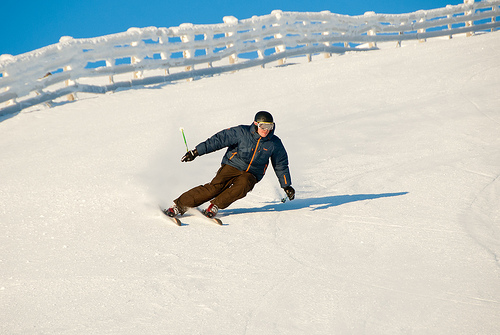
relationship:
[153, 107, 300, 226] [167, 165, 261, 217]
man wearing pants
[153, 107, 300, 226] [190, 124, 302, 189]
man wearing coat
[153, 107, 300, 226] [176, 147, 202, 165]
man wearing gloves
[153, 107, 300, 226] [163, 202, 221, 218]
man wearing boots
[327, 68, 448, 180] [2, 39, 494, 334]
snow on ground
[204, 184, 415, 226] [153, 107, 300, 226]
shadow of man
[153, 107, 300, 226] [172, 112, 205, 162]
man holds ski stick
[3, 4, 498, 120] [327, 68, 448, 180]
fence covered in snow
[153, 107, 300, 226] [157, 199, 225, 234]
man has two skis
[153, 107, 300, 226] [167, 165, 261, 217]
man wears pants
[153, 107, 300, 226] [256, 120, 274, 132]
man wears goggles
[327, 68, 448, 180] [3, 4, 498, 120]
snow covers fence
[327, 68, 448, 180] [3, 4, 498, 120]
snow covering fence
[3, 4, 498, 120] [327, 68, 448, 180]
fence covered with snow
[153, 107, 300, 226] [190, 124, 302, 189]
man wears coat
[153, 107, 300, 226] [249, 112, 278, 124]
man wearing helmet